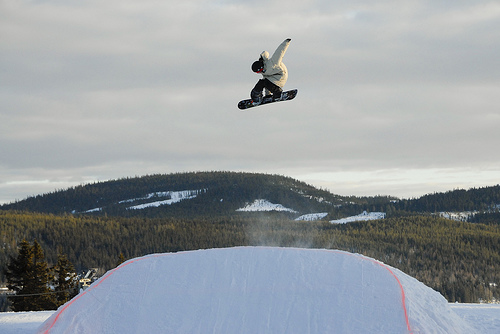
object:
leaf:
[477, 246, 488, 257]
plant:
[2, 238, 58, 312]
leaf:
[73, 242, 78, 248]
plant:
[47, 251, 80, 306]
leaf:
[368, 232, 373, 237]